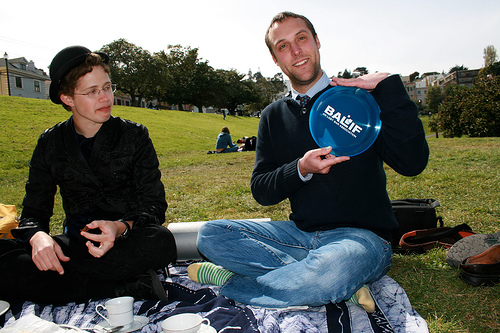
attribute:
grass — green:
[4, 96, 495, 329]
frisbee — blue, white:
[309, 86, 381, 162]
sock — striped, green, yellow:
[187, 260, 233, 287]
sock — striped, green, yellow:
[347, 284, 374, 312]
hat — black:
[49, 44, 112, 100]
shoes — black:
[110, 268, 167, 301]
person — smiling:
[189, 4, 430, 310]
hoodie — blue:
[215, 132, 234, 148]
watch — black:
[117, 219, 130, 240]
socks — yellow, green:
[189, 261, 376, 310]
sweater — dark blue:
[248, 74, 428, 239]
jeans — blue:
[198, 216, 393, 304]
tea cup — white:
[160, 314, 213, 330]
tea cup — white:
[97, 295, 135, 328]